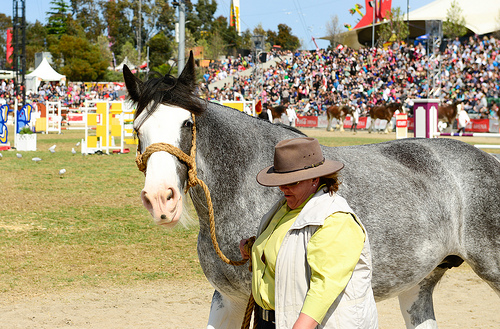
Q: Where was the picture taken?
A: At a horse show.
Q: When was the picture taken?
A: Daytime.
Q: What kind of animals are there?
A: Horses.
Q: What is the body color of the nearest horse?
A: Gray.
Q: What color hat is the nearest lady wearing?
A: Brown.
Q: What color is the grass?
A: Green.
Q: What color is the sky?
A: Blue.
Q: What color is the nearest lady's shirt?
A: Yellow.